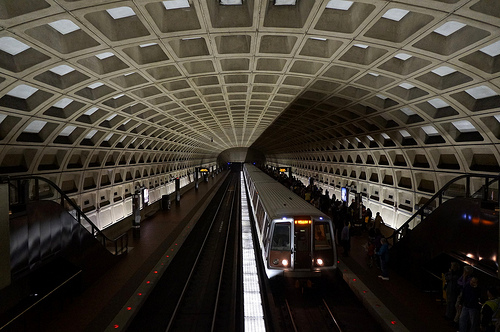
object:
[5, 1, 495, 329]
tunnel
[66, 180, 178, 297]
dock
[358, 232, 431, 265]
shirt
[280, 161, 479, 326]
platform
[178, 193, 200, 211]
ground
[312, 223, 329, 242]
driver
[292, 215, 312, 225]
sign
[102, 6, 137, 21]
glass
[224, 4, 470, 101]
cieling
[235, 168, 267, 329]
lights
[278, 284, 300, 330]
tracks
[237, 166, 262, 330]
divider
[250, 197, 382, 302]
subway train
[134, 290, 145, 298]
red light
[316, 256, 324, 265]
headlight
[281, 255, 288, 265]
headlight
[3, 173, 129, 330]
staircase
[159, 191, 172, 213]
trash receptacle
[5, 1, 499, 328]
subway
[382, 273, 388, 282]
shoes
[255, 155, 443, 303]
passengers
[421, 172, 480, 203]
railing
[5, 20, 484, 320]
station